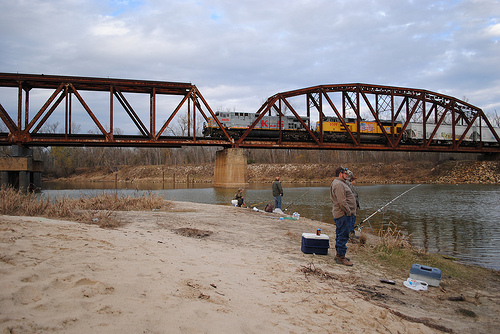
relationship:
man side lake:
[323, 162, 365, 265] [40, 170, 498, 293]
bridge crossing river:
[0, 72, 500, 154] [401, 187, 472, 234]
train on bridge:
[200, 105, 497, 142] [0, 63, 497, 160]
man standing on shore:
[270, 176, 282, 210] [164, 201, 496, 328]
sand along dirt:
[6, 186, 481, 332] [170, 222, 210, 238]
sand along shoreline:
[6, 186, 481, 332] [182, 194, 405, 239]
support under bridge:
[212, 145, 248, 190] [5, 60, 489, 167]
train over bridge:
[200, 111, 500, 146] [0, 72, 495, 195]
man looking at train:
[249, 167, 300, 214] [203, 112, 412, 141]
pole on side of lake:
[357, 181, 419, 231] [376, 162, 497, 252]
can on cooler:
[315, 227, 323, 236] [300, 232, 332, 255]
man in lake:
[330, 165, 362, 266] [161, 129, 458, 259]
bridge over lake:
[0, 72, 495, 195] [29, 182, 498, 272]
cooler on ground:
[300, 228, 327, 258] [38, 228, 255, 310]